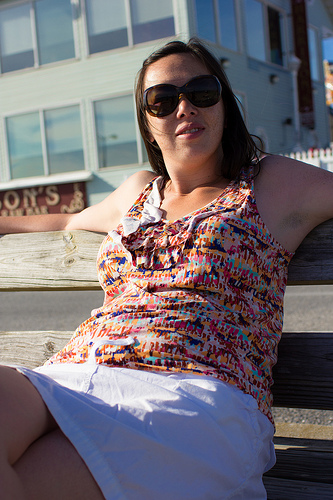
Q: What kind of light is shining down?
A: Sunlight.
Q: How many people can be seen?
A: One.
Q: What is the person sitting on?
A: A bench.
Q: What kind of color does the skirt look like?
A: White.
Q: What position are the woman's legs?
A: Crossed.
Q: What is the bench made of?
A: Wood.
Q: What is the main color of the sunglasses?
A: Brown.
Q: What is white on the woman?
A: Skirt.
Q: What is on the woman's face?
A: Sunglasses.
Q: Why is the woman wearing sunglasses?
A: Sunny.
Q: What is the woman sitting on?
A: Bench.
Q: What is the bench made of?
A: Wood.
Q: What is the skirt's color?
A: White.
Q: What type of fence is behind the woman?
A: Picket.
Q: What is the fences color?
A: White.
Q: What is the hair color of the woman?
A: Brown.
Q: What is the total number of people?
A: 1.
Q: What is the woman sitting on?
A: Bench.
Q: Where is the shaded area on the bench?
A: Lower right.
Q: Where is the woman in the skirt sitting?
A: Bench.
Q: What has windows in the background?
A: Building.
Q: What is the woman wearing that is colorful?
A: Top.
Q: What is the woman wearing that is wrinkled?
A: Skirt.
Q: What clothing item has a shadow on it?
A: Skirt.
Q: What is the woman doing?
A: She is sitting on a bench.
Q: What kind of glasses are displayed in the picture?
A: They are sunglasses.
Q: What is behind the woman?
A: A bar.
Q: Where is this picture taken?
A: Outside.